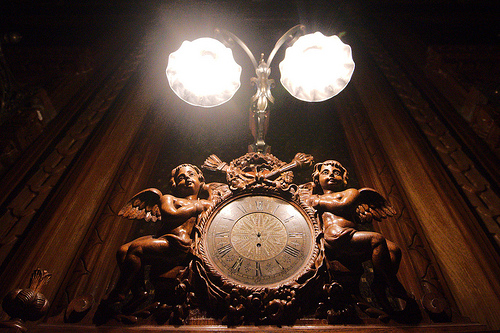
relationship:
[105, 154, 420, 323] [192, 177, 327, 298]
cherubs on clock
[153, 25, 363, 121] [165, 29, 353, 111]
lamps with sources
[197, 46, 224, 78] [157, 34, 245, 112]
bulb in shade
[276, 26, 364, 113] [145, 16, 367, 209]
edge on fixture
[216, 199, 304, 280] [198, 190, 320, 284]
numerals on face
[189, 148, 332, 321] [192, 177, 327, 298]
wood around clock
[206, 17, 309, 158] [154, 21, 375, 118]
metal supports lights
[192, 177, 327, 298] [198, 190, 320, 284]
clock has face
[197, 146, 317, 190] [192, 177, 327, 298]
scepter on clock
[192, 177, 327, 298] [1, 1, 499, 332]
clock in wall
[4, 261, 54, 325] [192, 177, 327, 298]
statue beside clock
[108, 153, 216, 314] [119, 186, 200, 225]
statue has wings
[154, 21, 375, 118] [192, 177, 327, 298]
lights on clock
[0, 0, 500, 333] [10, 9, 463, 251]
picture was taken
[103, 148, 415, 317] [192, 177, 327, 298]
statues beside clock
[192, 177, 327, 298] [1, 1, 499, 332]
clock on wall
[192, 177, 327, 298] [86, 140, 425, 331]
clock has decorations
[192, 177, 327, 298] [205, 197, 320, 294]
clock has numbers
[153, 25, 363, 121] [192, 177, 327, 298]
lamps over clock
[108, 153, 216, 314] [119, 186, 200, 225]
statue with wings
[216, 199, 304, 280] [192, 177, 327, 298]
numerals on clock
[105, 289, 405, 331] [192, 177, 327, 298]
base on clock